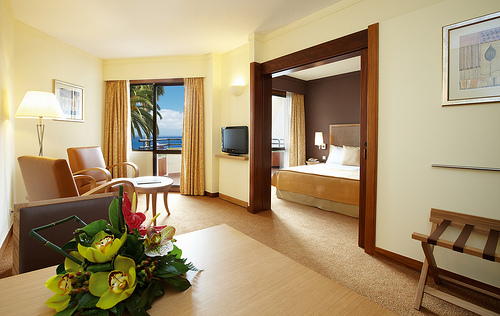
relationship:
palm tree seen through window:
[129, 82, 154, 137] [131, 85, 181, 184]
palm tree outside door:
[129, 82, 154, 137] [130, 84, 186, 176]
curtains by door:
[178, 78, 206, 196] [130, 84, 186, 176]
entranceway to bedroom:
[249, 21, 379, 254] [272, 74, 358, 210]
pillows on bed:
[328, 144, 361, 166] [277, 168, 360, 217]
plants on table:
[30, 185, 198, 316] [166, 296, 366, 315]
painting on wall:
[58, 81, 84, 123] [85, 59, 103, 146]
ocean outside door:
[133, 137, 145, 150] [130, 84, 186, 176]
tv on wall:
[219, 126, 248, 158] [206, 53, 218, 195]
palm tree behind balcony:
[129, 82, 154, 137] [140, 139, 183, 152]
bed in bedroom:
[277, 168, 360, 217] [272, 74, 358, 210]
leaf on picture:
[482, 44, 497, 62] [442, 12, 499, 111]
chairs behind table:
[68, 148, 137, 179] [136, 176, 174, 216]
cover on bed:
[289, 165, 358, 185] [277, 168, 360, 217]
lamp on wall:
[231, 74, 247, 93] [206, 53, 218, 195]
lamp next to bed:
[313, 132, 325, 151] [277, 168, 360, 217]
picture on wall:
[442, 12, 499, 111] [380, 0, 408, 247]